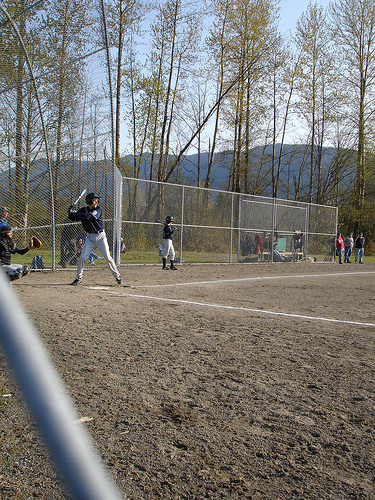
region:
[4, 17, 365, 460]
A baseball game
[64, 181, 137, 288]
A batter getting ready to bat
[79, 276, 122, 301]
The home plate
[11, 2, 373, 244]
Large and tall trees which are almost bare.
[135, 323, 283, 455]
Dirt on the baseball field.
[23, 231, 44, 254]
A brown baseball mit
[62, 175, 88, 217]
A baseball bat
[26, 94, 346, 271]
A metal fence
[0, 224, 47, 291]
An umpire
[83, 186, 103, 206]
A black baseball helmet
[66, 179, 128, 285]
A baseball player about to bat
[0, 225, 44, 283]
A baseball catcher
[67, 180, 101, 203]
a baseball bat about to be swung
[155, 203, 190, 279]
a baseball player preparing to bat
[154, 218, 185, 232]
A baseball bat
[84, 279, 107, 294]
A baseball plate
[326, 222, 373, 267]
A group of people watching baseball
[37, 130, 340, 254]
A chain link fence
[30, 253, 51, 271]
A blue bag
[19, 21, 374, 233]
trees behind the baseball field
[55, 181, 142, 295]
baseball player at bat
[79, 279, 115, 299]
home plate at baseball field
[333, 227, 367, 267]
spectators watching baseball game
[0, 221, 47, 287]
catcher behind home plate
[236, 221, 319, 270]
dugout at a baseball field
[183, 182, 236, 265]
silver metal fence at field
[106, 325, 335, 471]
dirt ground at a baseball field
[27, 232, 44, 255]
mitt of a catcher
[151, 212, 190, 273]
baseball player in batter's circle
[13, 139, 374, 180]
mountains in the distance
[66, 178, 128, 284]
BATTER IN WHITE AND BLACK UNIFORM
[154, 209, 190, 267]
PLAYER IN WHITE AND BLACK UNIFORM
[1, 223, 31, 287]
CATCHER IN WHITE AND BLACK UNIFORM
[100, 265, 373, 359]
WHITE LINES ON DIRT GROUND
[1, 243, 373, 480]
BROWN DIRT BASEBALL FIELD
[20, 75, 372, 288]
CHAIN LINK FENCE IN BACKGROUND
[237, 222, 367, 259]
SPECTATORS OF BASEBALL GAME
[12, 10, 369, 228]
TALL GREEN TREES BY BASEBALL FIELD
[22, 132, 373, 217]
MOUNTAINS OFF IN THE DISTANCE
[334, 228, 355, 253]
RED SHIRT ON SPECTATOR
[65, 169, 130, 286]
batter waiting for baseball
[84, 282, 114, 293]
home plate on baseball diamond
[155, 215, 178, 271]
baseball player carrying bat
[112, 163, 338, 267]
chain link fence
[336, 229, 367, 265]
spectators beside chain link fence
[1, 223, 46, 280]
catcher stooping to catch ball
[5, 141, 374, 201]
mountains in background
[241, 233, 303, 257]
jackets hung up behind fence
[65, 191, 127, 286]
baseball player in blue and white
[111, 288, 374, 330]
chalk line from home to first base